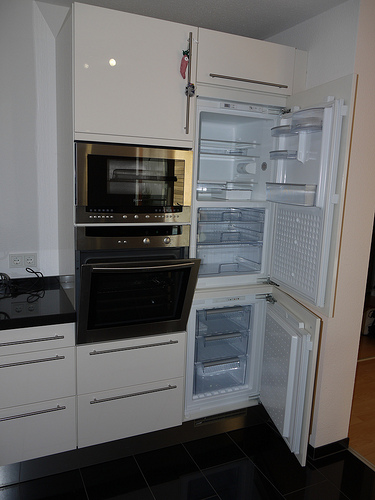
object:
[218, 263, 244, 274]
inside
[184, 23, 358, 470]
refrigerator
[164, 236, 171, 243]
knob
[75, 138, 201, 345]
oven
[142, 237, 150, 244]
knob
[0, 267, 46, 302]
cord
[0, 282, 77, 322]
counter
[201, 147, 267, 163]
shelf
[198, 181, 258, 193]
shelf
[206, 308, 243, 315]
handle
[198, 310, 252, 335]
drawer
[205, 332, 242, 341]
handle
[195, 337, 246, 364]
drawer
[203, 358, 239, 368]
handle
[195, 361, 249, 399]
drawer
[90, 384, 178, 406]
handle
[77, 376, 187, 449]
drawer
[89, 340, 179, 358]
handle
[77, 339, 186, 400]
drawer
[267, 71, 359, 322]
door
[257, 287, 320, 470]
door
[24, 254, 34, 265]
socket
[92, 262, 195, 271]
handle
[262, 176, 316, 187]
tray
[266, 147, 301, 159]
tray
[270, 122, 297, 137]
tray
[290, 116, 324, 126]
tray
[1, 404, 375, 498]
floor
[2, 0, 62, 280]
wall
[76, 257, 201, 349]
door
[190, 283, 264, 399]
cabinet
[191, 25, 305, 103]
cabinet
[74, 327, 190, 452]
cabinet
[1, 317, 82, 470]
cabinet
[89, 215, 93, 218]
button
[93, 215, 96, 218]
button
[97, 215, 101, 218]
button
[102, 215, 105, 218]
button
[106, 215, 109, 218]
button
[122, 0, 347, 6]
ceiling